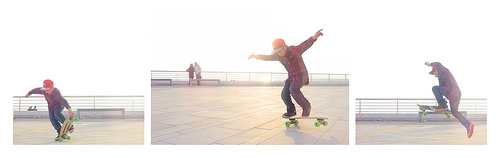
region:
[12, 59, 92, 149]
boy doing tricks on skateboard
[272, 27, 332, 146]
boy doing tricks on skateboard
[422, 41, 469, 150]
boy doing tricks on skateboard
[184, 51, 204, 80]
couple standing by fence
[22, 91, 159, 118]
tall fence in background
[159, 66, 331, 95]
tall fence in background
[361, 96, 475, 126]
tall fence in background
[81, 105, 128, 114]
bench near metal gate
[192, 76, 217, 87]
bench near metal gate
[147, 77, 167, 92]
bench near metal gate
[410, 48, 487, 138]
Person on a skate board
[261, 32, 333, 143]
Person on a skate board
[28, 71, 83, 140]
Person on a skate board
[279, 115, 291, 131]
Green wheel on skate board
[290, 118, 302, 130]
Green wheel on skate board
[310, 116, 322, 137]
Green wheel on skate board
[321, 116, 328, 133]
Green wheel on skate board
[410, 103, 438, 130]
Green wheel on skate board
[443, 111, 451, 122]
Green wheel on skate board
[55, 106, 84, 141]
Green wheel on skate board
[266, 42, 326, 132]
boy is on skateboard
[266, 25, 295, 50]
boy has red cap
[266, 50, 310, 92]
boy has checked shirt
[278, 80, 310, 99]
boy has blue jeans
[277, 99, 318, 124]
boy has black sneakers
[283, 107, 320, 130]
boy has black skateboard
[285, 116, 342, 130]
board has green wheels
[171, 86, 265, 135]
boy on grey concrete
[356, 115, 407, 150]
yellow line on concrete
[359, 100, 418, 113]
fence is behind boy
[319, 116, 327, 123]
a scathing board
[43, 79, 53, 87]
a red cap on the man's head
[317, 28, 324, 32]
a pointed finger of a man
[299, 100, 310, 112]
the leg of a man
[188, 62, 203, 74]
two people watching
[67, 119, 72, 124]
green wheel of a scatting board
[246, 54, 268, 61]
the hand of a man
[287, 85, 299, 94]
the knee of a man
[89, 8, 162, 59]
white skies in the background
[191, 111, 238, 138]
a well lit floor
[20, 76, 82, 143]
person on a skateboard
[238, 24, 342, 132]
person on a skateboard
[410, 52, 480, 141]
person on a skateboard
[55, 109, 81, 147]
skateboard with green wheels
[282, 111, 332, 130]
skateboard with green wheels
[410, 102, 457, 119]
skateboard with green wheels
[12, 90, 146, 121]
metal railing behind person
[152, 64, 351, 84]
metal railing behind person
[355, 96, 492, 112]
metal railing behind person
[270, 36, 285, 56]
red and grey hat